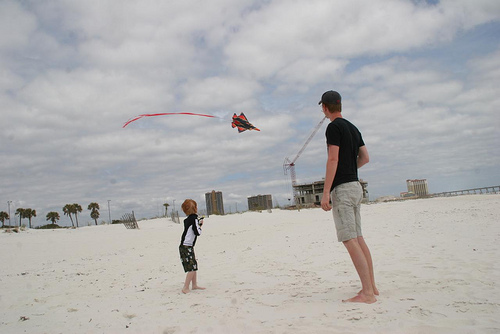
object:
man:
[318, 90, 380, 304]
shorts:
[331, 181, 364, 243]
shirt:
[324, 117, 365, 194]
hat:
[318, 89, 341, 105]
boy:
[178, 199, 207, 294]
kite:
[121, 112, 261, 133]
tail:
[121, 112, 221, 130]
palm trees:
[86, 203, 100, 226]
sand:
[1, 242, 499, 333]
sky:
[0, 1, 500, 230]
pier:
[383, 184, 500, 200]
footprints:
[425, 311, 451, 322]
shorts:
[178, 244, 199, 273]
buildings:
[205, 190, 225, 216]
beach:
[0, 193, 500, 333]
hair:
[181, 199, 198, 216]